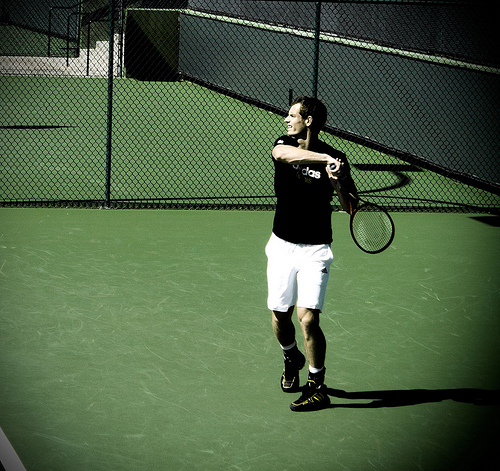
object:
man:
[263, 96, 358, 412]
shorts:
[264, 232, 333, 314]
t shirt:
[270, 135, 359, 246]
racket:
[330, 164, 396, 255]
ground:
[1, 76, 496, 464]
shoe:
[289, 366, 331, 412]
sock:
[278, 340, 296, 350]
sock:
[308, 364, 324, 373]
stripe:
[312, 396, 319, 401]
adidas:
[292, 164, 321, 179]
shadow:
[327, 386, 500, 410]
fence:
[1, 1, 497, 212]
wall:
[181, 1, 498, 192]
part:
[343, 189, 367, 212]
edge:
[267, 301, 294, 315]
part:
[266, 262, 294, 312]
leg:
[289, 268, 332, 412]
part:
[299, 314, 316, 332]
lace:
[299, 382, 314, 402]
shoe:
[280, 340, 306, 393]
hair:
[290, 95, 327, 134]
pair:
[280, 341, 332, 413]